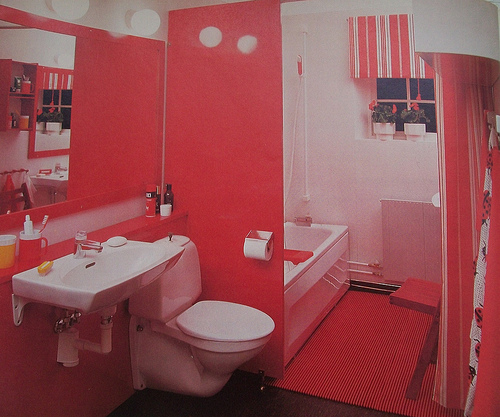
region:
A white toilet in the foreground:
[125, 225, 285, 405]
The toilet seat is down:
[133, 223, 286, 407]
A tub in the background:
[263, 194, 367, 369]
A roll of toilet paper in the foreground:
[236, 225, 278, 269]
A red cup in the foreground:
[15, 220, 62, 267]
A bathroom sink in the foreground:
[6, 225, 189, 382]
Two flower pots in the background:
[361, 92, 431, 149]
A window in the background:
[354, 59, 445, 149]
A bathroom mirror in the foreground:
[1, 9, 91, 225]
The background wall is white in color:
[284, 14, 494, 261]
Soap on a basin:
[104, 232, 129, 247]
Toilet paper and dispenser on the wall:
[232, 211, 279, 273]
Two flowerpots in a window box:
[365, 90, 435, 151]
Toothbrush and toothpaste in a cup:
[12, 209, 49, 263]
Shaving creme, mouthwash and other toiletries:
[140, 168, 180, 220]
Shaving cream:
[142, 174, 159, 222]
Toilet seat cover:
[167, 280, 277, 355]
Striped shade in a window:
[346, 9, 433, 93]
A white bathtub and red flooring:
[276, 184, 364, 381]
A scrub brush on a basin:
[35, 257, 57, 279]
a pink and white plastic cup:
[19, 200, 51, 266]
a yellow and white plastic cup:
[2, 230, 19, 270]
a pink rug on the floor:
[281, 287, 417, 414]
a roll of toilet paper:
[237, 218, 276, 272]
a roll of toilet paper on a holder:
[227, 215, 278, 273]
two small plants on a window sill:
[363, 101, 439, 136]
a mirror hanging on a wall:
[14, 25, 86, 214]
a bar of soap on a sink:
[103, 224, 140, 253]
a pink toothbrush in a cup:
[30, 207, 52, 234]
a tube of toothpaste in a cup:
[24, 212, 38, 248]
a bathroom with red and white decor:
[0, 0, 497, 415]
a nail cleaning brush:
[36, 257, 54, 272]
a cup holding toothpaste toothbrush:
[18, 214, 53, 266]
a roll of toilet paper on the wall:
[243, 230, 275, 265]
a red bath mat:
[271, 287, 465, 414]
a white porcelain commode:
[128, 234, 274, 399]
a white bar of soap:
[105, 235, 129, 247]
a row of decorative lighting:
[44, 0, 165, 37]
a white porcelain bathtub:
[281, 212, 351, 364]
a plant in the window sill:
[368, 99, 398, 144]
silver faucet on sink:
[66, 230, 111, 260]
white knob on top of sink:
[71, 229, 88, 239]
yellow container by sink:
[32, 258, 50, 277]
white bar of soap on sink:
[107, 228, 125, 245]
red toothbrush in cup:
[38, 212, 54, 231]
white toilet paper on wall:
[242, 232, 274, 257]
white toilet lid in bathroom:
[182, 291, 269, 342]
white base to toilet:
[134, 260, 272, 397]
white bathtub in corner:
[278, 222, 353, 322]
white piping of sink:
[64, 333, 111, 365]